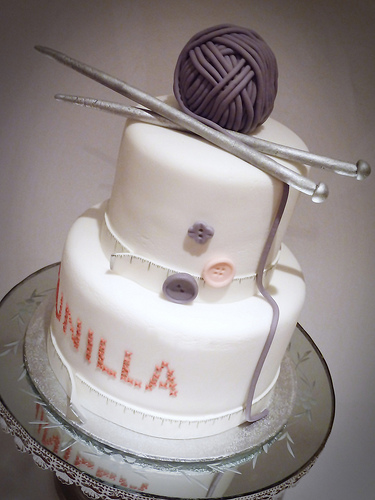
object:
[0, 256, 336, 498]
plate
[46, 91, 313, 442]
themed cake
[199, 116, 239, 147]
yarn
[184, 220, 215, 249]
button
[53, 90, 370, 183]
knitting needle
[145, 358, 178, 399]
letter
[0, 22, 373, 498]
sculpure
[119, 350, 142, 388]
letter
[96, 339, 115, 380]
letter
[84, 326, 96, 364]
letter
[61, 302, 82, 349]
letter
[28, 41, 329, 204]
nail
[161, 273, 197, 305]
button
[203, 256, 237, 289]
button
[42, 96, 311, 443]
cake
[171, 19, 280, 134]
ball